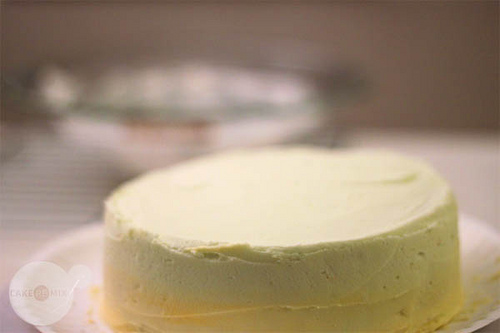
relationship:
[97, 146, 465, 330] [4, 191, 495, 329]
cake on plate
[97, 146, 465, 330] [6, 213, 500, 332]
cake on dish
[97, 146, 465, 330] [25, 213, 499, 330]
cake on plate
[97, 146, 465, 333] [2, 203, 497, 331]
cake on dish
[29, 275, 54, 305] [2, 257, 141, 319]
number in logo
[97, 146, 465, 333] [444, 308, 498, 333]
cake on a plate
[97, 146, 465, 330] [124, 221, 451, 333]
cake on a plate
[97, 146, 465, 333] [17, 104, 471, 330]
cake of dessert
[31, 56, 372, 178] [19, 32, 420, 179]
bowl of bowl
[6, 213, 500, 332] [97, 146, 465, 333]
dish has cake